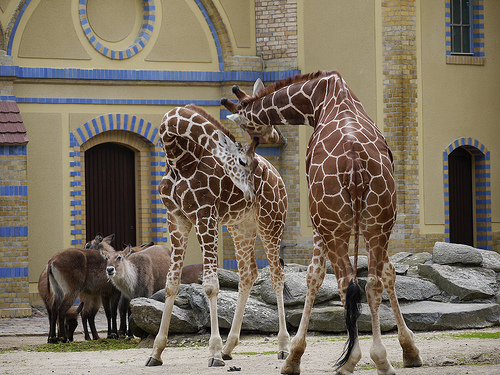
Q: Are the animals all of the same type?
A: No, there are both giraffes and deer.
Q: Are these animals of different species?
A: Yes, they are giraffes and deer.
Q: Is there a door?
A: Yes, there is a door.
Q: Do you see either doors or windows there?
A: Yes, there is a door.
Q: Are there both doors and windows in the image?
A: Yes, there are both a door and a window.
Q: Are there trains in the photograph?
A: No, there are no trains.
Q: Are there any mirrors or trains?
A: No, there are no trains or mirrors.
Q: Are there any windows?
A: Yes, there is a window.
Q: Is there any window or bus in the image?
A: Yes, there is a window.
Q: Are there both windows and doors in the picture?
A: Yes, there are both a window and a door.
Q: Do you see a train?
A: No, there are no trains.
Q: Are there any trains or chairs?
A: No, there are no trains or chairs.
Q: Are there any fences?
A: No, there are no fences.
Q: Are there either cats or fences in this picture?
A: No, there are no fences or cats.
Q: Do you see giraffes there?
A: Yes, there is a giraffe.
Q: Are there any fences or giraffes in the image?
A: Yes, there is a giraffe.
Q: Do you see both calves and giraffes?
A: No, there is a giraffe but no calves.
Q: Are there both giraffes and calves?
A: No, there is a giraffe but no calves.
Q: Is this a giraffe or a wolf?
A: This is a giraffe.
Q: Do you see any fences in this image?
A: No, there are no fences.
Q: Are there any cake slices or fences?
A: No, there are no fences or cake slices.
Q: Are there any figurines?
A: No, there are no figurines.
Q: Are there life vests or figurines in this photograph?
A: No, there are no figurines or life vests.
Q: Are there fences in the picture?
A: No, there are no fences.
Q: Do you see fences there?
A: No, there are no fences.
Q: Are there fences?
A: No, there are no fences.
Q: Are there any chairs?
A: No, there are no chairs.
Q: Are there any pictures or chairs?
A: No, there are no chairs or pictures.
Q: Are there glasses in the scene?
A: No, there are no glasses.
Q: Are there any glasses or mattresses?
A: No, there are no glasses or mattresses.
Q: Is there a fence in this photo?
A: No, there are no fences.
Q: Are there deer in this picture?
A: Yes, there is a deer.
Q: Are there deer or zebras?
A: Yes, there is a deer.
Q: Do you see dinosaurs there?
A: No, there are no dinosaurs.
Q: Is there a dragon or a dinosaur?
A: No, there are no dinosaurs or dragons.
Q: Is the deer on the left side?
A: Yes, the deer is on the left of the image.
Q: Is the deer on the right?
A: No, the deer is on the left of the image.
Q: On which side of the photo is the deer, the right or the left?
A: The deer is on the left of the image.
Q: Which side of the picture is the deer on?
A: The deer is on the left of the image.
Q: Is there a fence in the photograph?
A: No, there are no fences.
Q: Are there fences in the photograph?
A: No, there are no fences.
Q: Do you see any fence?
A: No, there are no fences.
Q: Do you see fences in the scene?
A: No, there are no fences.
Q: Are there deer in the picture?
A: Yes, there is a deer.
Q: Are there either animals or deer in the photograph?
A: Yes, there is a deer.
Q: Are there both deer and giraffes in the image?
A: Yes, there are both a deer and a giraffe.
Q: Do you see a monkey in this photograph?
A: No, there are no monkeys.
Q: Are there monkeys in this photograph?
A: No, there are no monkeys.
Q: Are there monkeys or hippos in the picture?
A: No, there are no monkeys or hippos.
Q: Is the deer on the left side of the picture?
A: Yes, the deer is on the left of the image.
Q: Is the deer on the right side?
A: No, the deer is on the left of the image.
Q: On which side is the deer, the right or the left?
A: The deer is on the left of the image.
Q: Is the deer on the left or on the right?
A: The deer is on the left of the image.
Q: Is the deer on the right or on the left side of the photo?
A: The deer is on the left of the image.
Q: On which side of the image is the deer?
A: The deer is on the left of the image.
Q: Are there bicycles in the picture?
A: No, there are no bicycles.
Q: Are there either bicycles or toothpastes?
A: No, there are no bicycles or toothpastes.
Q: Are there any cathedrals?
A: No, there are no cathedrals.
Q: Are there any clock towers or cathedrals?
A: No, there are no cathedrals or clock towers.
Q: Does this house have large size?
A: Yes, the house is large.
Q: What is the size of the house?
A: The house is large.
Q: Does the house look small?
A: No, the house is large.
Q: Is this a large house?
A: Yes, this is a large house.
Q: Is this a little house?
A: No, this is a large house.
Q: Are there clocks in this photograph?
A: No, there are no clocks.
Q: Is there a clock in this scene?
A: No, there are no clocks.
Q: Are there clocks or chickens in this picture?
A: No, there are no clocks or chickens.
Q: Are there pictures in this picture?
A: No, there are no pictures.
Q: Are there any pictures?
A: No, there are no pictures.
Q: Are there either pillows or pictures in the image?
A: No, there are no pictures or pillows.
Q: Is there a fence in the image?
A: No, there are no fences.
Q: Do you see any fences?
A: No, there are no fences.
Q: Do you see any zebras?
A: No, there are no zebras.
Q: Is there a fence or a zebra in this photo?
A: No, there are no zebras or fences.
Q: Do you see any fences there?
A: No, there are no fences.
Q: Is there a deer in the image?
A: Yes, there is a deer.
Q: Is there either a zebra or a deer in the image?
A: Yes, there is a deer.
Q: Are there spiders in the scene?
A: No, there are no spiders.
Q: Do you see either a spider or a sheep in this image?
A: No, there are no spiders or sheep.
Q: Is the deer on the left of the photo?
A: Yes, the deer is on the left of the image.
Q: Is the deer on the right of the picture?
A: No, the deer is on the left of the image.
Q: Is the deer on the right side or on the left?
A: The deer is on the left of the image.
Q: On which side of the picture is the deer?
A: The deer is on the left of the image.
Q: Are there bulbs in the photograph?
A: No, there are no bulbs.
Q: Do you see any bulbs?
A: No, there are no bulbs.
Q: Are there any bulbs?
A: No, there are no bulbs.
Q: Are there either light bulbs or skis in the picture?
A: No, there are no light bulbs or skis.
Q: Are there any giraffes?
A: Yes, there is a giraffe.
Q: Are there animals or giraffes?
A: Yes, there is a giraffe.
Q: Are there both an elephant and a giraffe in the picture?
A: No, there is a giraffe but no elephants.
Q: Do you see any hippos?
A: No, there are no hippos.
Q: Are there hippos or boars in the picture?
A: No, there are no hippos or boars.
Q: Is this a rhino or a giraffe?
A: This is a giraffe.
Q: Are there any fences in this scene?
A: No, there are no fences.